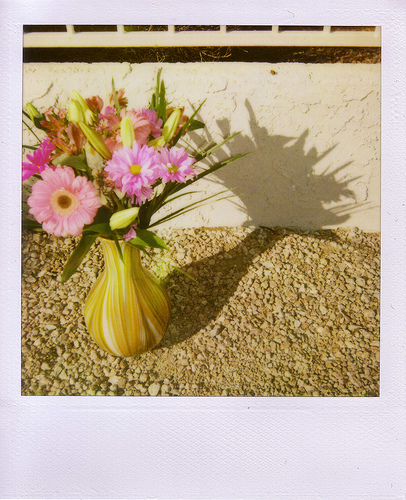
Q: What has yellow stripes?
A: The vase.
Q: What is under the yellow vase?
A: Beige gravel.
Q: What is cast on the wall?
A: A shadow of the vase and flowers.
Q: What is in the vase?
A: Pink flowers.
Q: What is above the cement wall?
A: A white railing.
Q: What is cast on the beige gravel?
A: Shadow of vase.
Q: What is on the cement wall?
A: Shadow of flowers.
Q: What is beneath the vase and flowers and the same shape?
A: The shadow of the vase and flpwers.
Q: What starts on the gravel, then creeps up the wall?
A: The shadow of the vase and flowers.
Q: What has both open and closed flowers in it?
A: A bouquet, in a vase.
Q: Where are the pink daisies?
A: In a green vase.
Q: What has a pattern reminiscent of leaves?
A: The vase, holding the flowers.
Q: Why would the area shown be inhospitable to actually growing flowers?
A: It is full of rocks.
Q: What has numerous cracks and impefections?
A: The white wall. behind the gravel bed.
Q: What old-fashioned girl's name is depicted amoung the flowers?
A: Daisy.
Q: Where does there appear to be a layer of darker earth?
A: In a bed, above the cement wall, backing the gravel bed.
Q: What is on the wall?
A: Shadow.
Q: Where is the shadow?
A: On wall.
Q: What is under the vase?
A: Rocks.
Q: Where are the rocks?
A: On the ground.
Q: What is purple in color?
A: Flowers.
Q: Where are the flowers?
A: In vase.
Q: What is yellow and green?
A: Vase.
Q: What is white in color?
A: The wall.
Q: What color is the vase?
A: Yellow.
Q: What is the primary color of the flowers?
A: Pink.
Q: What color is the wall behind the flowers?
A: White.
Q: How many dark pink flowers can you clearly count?
A: 1.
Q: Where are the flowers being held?
A: Vase.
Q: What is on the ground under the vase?
A: Rock.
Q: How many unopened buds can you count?
A: 5.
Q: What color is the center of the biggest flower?
A: Brown.